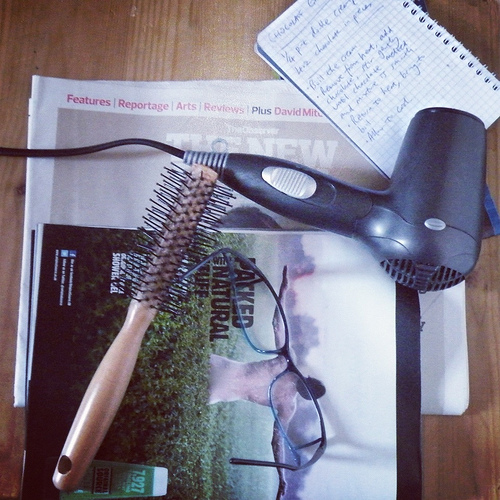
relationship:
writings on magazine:
[64, 90, 324, 119] [10, 72, 470, 417]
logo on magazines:
[66, 247, 76, 260] [26, 217, 408, 499]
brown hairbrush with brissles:
[30, 160, 235, 493] [135, 167, 219, 285]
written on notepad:
[329, 65, 399, 147] [254, 0, 499, 182]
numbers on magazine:
[129, 467, 146, 497] [15, 73, 415, 498]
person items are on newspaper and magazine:
[122, 314, 324, 390] [19, 221, 425, 498]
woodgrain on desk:
[438, 398, 486, 483] [23, 4, 486, 486]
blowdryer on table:
[178, 106, 487, 294] [39, 51, 110, 88]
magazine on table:
[19, 221, 425, 498] [2, 1, 496, 498]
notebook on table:
[0, 99, 327, 364] [78, 51, 188, 89]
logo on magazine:
[52, 248, 77, 310] [19, 221, 425, 498]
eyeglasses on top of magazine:
[164, 248, 328, 488] [97, 254, 284, 354]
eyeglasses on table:
[164, 248, 328, 488] [395, 117, 498, 499]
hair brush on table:
[129, 171, 208, 348] [62, 179, 122, 274]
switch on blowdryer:
[256, 165, 320, 199] [178, 106, 487, 294]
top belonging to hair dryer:
[382, 108, 483, 246] [355, 109, 483, 312]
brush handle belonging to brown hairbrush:
[38, 304, 158, 492] [30, 160, 235, 493]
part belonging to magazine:
[301, 235, 402, 498] [2, 202, 449, 499]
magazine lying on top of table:
[19, 221, 425, 498] [2, 1, 496, 498]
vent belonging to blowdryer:
[375, 253, 475, 296] [178, 106, 487, 294]